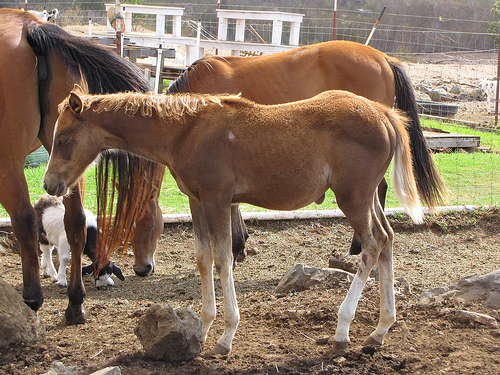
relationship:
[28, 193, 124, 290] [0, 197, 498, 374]
goat sniffing ground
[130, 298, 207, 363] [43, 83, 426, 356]
rock near horse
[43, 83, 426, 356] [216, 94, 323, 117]
horse has back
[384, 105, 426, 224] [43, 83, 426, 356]
tail of horse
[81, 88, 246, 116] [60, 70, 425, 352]
hair of horse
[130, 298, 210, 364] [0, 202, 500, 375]
rock in brown dirt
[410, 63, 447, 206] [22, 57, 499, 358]
tail of horse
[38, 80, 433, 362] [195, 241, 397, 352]
horse with legs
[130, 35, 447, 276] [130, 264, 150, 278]
horse with nose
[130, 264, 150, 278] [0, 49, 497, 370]
nose to ground